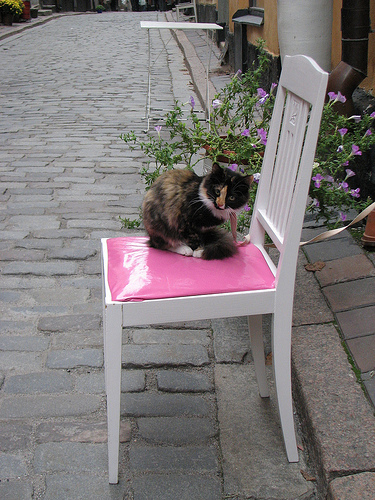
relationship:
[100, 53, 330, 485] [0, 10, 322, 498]
chair on sidewalk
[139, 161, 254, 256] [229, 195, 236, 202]
cat has eye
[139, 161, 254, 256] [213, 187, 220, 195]
cat has eye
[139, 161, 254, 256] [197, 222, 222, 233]
cat has stomach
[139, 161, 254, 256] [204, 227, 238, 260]
cat has tail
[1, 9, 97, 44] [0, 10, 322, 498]
edge of sidewalk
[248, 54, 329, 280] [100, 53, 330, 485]
back of chair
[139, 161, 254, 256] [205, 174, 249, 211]
cat has face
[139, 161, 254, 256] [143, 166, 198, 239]
cat has back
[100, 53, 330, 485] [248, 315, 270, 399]
chair has back leg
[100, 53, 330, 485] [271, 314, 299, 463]
chair has back leg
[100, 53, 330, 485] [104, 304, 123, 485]
chair has front leg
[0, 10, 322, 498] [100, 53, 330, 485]
sidewalk under chair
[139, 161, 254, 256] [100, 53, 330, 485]
cat on chair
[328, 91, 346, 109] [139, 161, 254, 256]
flower behind cat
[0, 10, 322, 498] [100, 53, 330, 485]
sidewalk beneath chair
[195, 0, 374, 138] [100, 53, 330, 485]
wall behind chair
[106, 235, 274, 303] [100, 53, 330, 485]
seat of chair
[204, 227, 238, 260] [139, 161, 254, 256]
tail of cat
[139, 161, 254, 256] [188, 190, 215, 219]
cat has whiskers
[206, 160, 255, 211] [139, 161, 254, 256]
head of cat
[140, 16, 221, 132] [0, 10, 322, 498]
tray table on sidewalk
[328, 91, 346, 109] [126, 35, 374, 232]
flower on bush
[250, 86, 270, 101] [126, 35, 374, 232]
flower on bush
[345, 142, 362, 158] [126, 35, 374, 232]
flower on bush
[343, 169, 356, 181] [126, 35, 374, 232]
flower on bush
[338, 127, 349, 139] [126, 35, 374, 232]
flower on bush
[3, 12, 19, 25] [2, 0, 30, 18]
pot of flowers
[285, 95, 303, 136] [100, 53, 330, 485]
design on chair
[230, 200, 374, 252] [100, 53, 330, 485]
leash on chair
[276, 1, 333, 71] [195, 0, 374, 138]
pillar on wall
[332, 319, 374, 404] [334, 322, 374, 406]
grass in crack